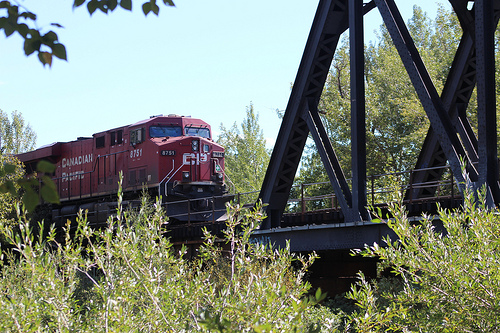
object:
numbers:
[129, 148, 143, 158]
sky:
[1, 0, 475, 172]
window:
[130, 130, 142, 144]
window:
[150, 122, 184, 139]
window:
[183, 125, 209, 139]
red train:
[1, 114, 238, 229]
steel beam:
[301, 110, 356, 222]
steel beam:
[364, 0, 495, 215]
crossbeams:
[243, 0, 498, 225]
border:
[8, 0, 497, 254]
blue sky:
[0, 0, 279, 103]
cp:
[182, 152, 209, 166]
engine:
[17, 114, 234, 230]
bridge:
[271, 0, 500, 253]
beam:
[245, 0, 345, 228]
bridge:
[1, 159, 498, 255]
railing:
[1, 183, 498, 240]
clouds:
[78, 59, 257, 91]